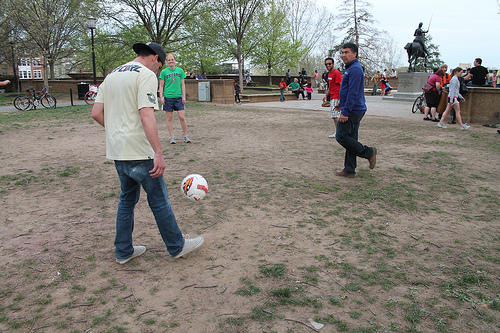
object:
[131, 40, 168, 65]
hat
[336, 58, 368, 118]
blue shirt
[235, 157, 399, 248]
grass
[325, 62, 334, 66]
glasses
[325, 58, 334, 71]
face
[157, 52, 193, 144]
person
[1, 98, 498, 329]
dirt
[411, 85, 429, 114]
bike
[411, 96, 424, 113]
tire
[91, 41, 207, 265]
guy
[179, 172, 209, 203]
ball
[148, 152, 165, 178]
hand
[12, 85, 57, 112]
bicycles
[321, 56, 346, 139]
man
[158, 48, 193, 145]
soccer player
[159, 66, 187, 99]
shirt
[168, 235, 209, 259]
shoe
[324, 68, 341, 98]
t-shirt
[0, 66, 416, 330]
park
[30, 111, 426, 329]
area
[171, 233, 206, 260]
foot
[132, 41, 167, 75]
head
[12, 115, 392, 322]
ground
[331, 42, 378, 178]
man